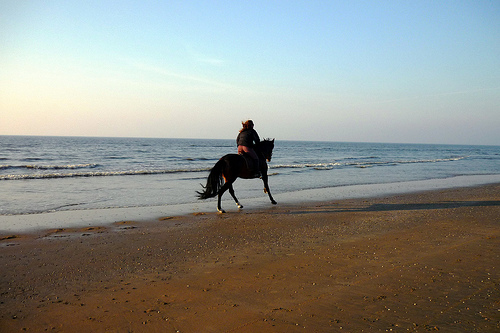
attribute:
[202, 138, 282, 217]
horse — brown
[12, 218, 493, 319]
beach — present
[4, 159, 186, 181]
waves — small, low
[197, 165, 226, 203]
tail — black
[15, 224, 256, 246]
sand — brown, wet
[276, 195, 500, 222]
shadow — present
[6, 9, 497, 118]
sky — cloudy, blue, clear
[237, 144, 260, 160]
pants — red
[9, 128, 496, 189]
ocean — brown, blue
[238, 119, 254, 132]
hair — brown